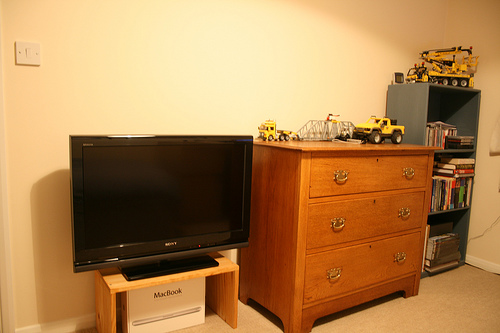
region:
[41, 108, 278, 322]
flat screen television on stand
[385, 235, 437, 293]
wooden drawer on furniture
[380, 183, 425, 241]
wooden drawer on furniture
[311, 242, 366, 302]
wooden drawer on furniture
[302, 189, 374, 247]
wooden drawer on furniture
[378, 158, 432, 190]
wooden drawer on furniture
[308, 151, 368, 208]
wooden drawer on furniture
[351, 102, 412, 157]
toy trucks on furniture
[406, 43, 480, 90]
Yellow model truck on a bookshelf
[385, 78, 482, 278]
Tall gray three shelf bookshelf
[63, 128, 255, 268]
Large black flatscreen television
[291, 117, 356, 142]
White model draw bridge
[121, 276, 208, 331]
White box under a television stand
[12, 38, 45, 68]
White wall mounted light switch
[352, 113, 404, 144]
Yellow monster truck on a dresser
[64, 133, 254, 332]
Television on a wood stand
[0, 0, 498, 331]
Room with white walls and cream carpet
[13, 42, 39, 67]
switch board fixed on wall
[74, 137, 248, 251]
black color television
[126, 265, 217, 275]
stand of the television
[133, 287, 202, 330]
MacBook mentioned on box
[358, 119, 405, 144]
yellow color toy truck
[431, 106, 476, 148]
books arrange on shelves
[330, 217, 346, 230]
decorative handles fixed to draws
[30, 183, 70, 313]
shadow of television falling on wall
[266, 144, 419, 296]
polished wooden furniture with draws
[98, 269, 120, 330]
wooden table on which television is placed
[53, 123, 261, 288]
flat screen tv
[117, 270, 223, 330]
macbook box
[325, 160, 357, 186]
drawer handles on chest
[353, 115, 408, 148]
toy yellow truck on top of wooden chest of drawers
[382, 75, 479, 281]
grey bookcase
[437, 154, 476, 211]
books on book shelf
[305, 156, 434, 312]
three wooden drawers on chest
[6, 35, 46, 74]
white plate on wall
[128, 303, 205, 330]
silver laptop on front of macbook box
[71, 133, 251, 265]
black flat screen tv.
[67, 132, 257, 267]
the tv is black/.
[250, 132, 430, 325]
the chest of drawers is brown.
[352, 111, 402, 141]
yellow toy truck on chest.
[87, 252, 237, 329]
tan colored tv stand.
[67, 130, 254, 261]
black LED tv set.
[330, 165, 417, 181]
chest of drawer pull knobs.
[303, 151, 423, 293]
the chest has three drawers.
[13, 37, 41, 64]
light switch on the wall.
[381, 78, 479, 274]
gray book shelf in corner.